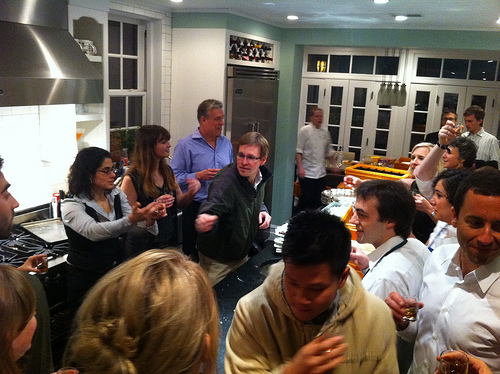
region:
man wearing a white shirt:
[296, 114, 362, 200]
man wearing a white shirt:
[356, 228, 433, 330]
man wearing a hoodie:
[219, 244, 413, 371]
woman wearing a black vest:
[61, 192, 136, 279]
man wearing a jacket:
[191, 152, 276, 266]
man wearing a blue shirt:
[174, 118, 265, 214]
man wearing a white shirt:
[406, 223, 497, 368]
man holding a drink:
[387, 263, 442, 335]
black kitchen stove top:
[3, 221, 81, 263]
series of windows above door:
[306, 48, 403, 83]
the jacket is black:
[194, 160, 294, 265]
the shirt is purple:
[162, 121, 248, 228]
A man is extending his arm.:
[196, 149, 250, 254]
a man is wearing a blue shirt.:
[189, 123, 227, 186]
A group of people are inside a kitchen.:
[279, 103, 499, 343]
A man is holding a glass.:
[391, 253, 486, 330]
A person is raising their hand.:
[415, 104, 470, 200]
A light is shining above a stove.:
[0, 96, 113, 136]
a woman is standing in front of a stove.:
[63, 160, 166, 258]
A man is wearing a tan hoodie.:
[251, 286, 413, 349]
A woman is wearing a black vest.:
[58, 203, 130, 268]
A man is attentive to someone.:
[458, 183, 498, 285]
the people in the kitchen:
[0, 99, 498, 372]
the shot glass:
[402, 295, 418, 322]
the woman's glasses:
[96, 167, 119, 174]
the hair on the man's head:
[279, 208, 351, 279]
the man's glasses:
[235, 149, 262, 162]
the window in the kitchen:
[105, 11, 146, 159]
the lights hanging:
[376, 45, 407, 107]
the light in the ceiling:
[287, 12, 298, 21]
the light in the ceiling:
[372, 0, 388, 4]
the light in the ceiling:
[394, 15, 407, 22]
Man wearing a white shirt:
[407, 159, 499, 373]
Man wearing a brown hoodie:
[225, 210, 401, 373]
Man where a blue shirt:
[172, 93, 239, 202]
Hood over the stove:
[0, 2, 110, 109]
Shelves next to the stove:
[68, 3, 118, 165]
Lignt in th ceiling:
[272, 3, 305, 30]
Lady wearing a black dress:
[54, 138, 161, 293]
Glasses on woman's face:
[92, 157, 119, 182]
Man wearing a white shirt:
[332, 159, 429, 319]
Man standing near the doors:
[287, 97, 336, 203]